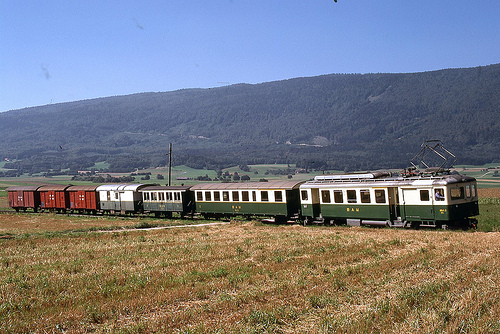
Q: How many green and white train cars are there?
A: Two.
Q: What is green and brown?
A: Grass.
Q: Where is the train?
A: On train tracks.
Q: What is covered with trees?
A: A hill.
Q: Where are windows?
A: On the train.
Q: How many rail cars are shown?
A: 7.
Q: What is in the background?
A: A hill.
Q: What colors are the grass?
A: Green and brown.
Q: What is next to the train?
A: A field.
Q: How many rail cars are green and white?
A: 2.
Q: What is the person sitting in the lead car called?
A: An engineer.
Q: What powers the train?
A: Electricity.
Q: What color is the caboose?
A: Red.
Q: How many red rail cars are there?
A: 3.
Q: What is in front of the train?
A: Grassy field.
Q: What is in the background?
A: Mountains.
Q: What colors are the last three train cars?
A: Red.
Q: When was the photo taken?
A: During the daytime.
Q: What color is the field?
A: Brown.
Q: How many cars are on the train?
A: Seven.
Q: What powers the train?
A: Electricity.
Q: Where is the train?
A: In the country.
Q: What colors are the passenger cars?
A: White and green.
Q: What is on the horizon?
A: A mountain.